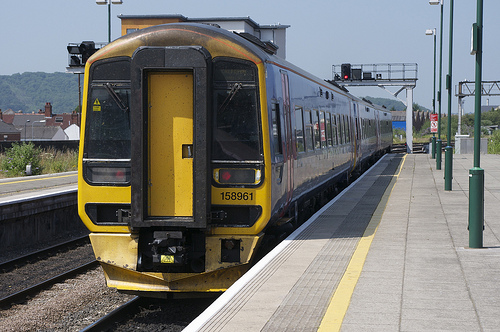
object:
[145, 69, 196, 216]
door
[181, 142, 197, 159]
handle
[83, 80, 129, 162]
window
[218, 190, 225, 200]
number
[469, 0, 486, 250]
poles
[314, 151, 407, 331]
line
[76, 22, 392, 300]
train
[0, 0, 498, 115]
sky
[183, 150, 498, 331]
platform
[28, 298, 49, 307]
gravel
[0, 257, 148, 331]
tracks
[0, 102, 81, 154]
buildings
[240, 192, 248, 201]
numbers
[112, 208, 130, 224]
metal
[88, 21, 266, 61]
roof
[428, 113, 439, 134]
sign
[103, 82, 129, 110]
wiper